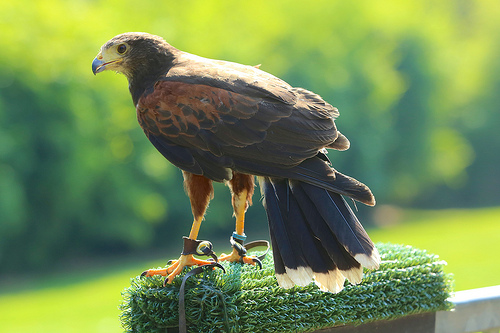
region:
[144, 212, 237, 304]
the sharp bird talon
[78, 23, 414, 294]
a fierce looking hawk perches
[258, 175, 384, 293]
the feathers on the rear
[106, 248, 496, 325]
a green mat on the perch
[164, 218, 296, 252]
a teather on the birds leg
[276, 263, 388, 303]
the white tips of the feathers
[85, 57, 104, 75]
the curved beak of the bird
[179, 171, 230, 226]
the feathers on the legs resemble fur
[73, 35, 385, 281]
a very dangerous predator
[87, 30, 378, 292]
a large bird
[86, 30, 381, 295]
a pradatory bird for game hunting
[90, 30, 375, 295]
a domesticated bird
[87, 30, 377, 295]
a game hunting bird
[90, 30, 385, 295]
a hawk for hunting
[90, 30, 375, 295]
a domesticated hawk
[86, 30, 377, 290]
a game hawk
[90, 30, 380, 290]
a brown coloured hawk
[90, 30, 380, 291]
a big bird for game hunting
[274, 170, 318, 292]
large black bird feather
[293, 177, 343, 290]
large black bird feather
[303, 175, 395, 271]
large black bird feather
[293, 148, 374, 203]
large black bird feather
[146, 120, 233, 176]
large black bird feather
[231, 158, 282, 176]
large black bird feather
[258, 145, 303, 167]
large black bird feather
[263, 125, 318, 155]
large black bird feather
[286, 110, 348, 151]
large black bird feather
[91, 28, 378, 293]
A brown colored hawk.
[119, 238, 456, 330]
A green bird perch.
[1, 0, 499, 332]
A bright green background.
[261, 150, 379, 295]
Brown and white tail.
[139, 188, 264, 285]
Pair of bird legs.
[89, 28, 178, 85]
A brown hawks head.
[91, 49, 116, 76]
Yellow and black bird beak.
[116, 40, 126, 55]
Brown colored bird eye.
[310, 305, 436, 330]
Brown piece of wood.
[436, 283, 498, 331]
A white colored wall.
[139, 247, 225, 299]
the claws of an eagle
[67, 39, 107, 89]
the beak of an eagle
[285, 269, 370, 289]
feathers with white tips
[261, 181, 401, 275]
feathers of an eagle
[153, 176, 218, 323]
legs of an eagle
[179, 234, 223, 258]
cuffs around the eagles leg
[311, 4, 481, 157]
green bushes in the background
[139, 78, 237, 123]
brown feather on the eagle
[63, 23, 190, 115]
the head of an eagle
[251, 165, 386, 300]
dark brown tail feathers with white tips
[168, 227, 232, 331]
a leather leg strap on a hawk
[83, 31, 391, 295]
a hawk with bright yellow feet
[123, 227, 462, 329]
a small patch of green astro turf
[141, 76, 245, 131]
a few light brown wing feathers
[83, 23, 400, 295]
A bird.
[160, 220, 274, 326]
A tether tied to the bird's legs.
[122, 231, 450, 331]
A green covered perch.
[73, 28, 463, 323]
The bird stands on a green rail.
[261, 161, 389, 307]
Black and white tail feathers on the bird.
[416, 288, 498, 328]
A railing under the green covering.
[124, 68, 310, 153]
Brown and tan feathers on the bird.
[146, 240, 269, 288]
Orange talons on the bird.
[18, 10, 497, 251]
A row of trees in the distance.